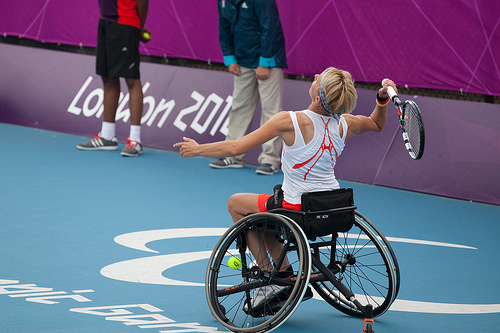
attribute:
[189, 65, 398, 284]
woman — blonde, disabled, female, preparing, sitting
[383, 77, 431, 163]
racket — black, white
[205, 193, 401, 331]
wheelchair — black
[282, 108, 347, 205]
tank top — white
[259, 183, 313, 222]
shorts — red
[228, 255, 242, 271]
ball — green, yellow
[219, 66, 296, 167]
pants — khaki, tan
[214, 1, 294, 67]
jacket — teal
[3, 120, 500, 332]
floor — blue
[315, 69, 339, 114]
headband — blue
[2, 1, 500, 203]
background — purple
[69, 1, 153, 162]
ball runner — standing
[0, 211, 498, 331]
lettering — white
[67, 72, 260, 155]
london 2010 — white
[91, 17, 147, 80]
shorts — black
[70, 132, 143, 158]
sneakers — grey, white, black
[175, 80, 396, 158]
arms — muscular